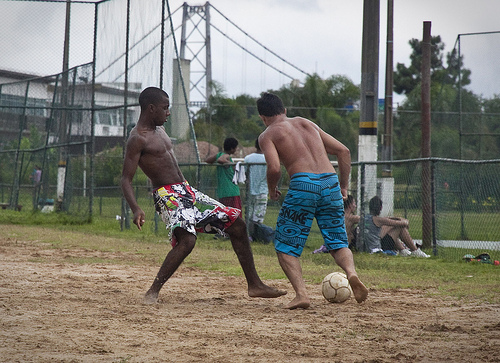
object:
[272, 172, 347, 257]
short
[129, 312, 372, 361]
ground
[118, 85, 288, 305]
man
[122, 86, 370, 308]
boys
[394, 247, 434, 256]
shoes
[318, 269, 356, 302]
ball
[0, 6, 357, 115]
bridge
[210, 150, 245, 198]
t-shirt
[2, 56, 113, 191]
fence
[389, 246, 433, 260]
sneakers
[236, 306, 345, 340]
dirt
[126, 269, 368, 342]
field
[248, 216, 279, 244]
backpack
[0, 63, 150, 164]
building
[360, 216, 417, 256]
trunks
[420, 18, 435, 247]
pole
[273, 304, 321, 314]
footprints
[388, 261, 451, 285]
grass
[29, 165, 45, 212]
girl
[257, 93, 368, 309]
man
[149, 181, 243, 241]
shorts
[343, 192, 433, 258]
person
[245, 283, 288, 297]
foot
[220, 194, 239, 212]
shorts